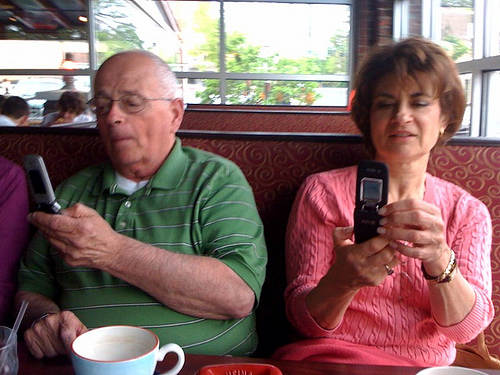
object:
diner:
[48, 85, 89, 125]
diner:
[1, 94, 33, 129]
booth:
[217, 128, 325, 219]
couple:
[14, 35, 496, 370]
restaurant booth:
[19, 119, 498, 357]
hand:
[330, 223, 403, 294]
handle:
[155, 339, 185, 373]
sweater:
[285, 166, 497, 369]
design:
[386, 266, 396, 360]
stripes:
[189, 193, 265, 228]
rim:
[0, 321, 32, 361]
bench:
[2, 127, 497, 369]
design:
[450, 146, 497, 190]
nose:
[110, 103, 126, 124]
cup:
[61, 320, 189, 375]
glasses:
[80, 91, 173, 113]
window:
[5, 6, 495, 125]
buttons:
[120, 220, 128, 228]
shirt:
[12, 135, 269, 357]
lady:
[275, 33, 491, 361]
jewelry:
[385, 264, 396, 276]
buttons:
[124, 200, 132, 209]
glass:
[1, 298, 36, 375]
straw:
[4, 300, 36, 338]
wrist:
[428, 245, 468, 288]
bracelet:
[420, 249, 458, 285]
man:
[11, 49, 270, 359]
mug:
[67, 322, 179, 372]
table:
[24, 335, 437, 373]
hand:
[30, 197, 120, 274]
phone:
[22, 155, 60, 217]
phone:
[351, 159, 390, 245]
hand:
[377, 198, 447, 261]